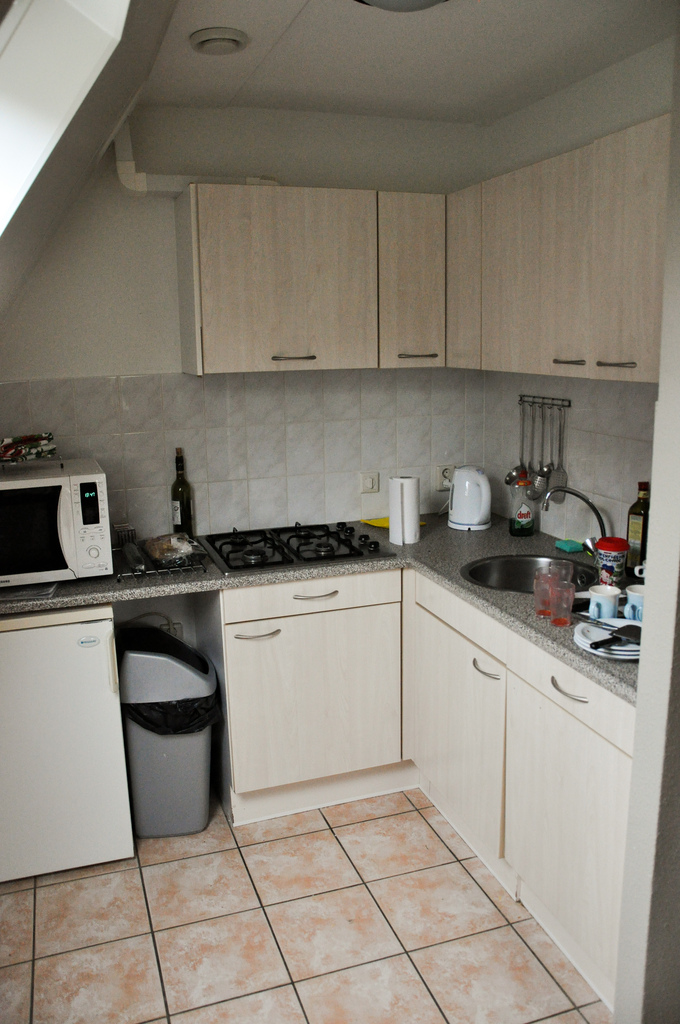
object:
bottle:
[171, 446, 192, 539]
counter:
[0, 510, 636, 704]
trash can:
[115, 618, 222, 839]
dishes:
[538, 537, 644, 668]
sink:
[464, 551, 598, 592]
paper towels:
[388, 476, 420, 545]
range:
[205, 518, 382, 572]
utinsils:
[504, 388, 571, 501]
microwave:
[0, 457, 113, 588]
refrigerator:
[1, 602, 132, 889]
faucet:
[542, 485, 609, 542]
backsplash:
[0, 378, 659, 553]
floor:
[2, 789, 613, 1021]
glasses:
[532, 559, 577, 627]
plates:
[571, 614, 641, 663]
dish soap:
[509, 469, 535, 537]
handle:
[272, 354, 317, 360]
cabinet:
[173, 187, 379, 378]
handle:
[400, 350, 446, 359]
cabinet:
[378, 184, 447, 370]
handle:
[552, 358, 588, 366]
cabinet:
[482, 139, 594, 375]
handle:
[594, 359, 633, 373]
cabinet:
[591, 110, 669, 383]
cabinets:
[171, 110, 675, 375]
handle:
[294, 591, 337, 600]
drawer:
[225, 569, 405, 627]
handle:
[550, 670, 587, 708]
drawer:
[407, 569, 638, 761]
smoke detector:
[191, 27, 249, 57]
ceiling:
[2, 2, 677, 123]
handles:
[270, 350, 639, 370]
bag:
[129, 674, 219, 732]